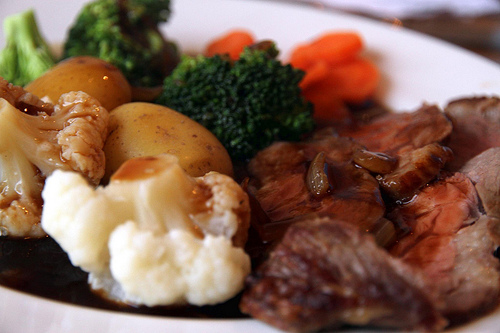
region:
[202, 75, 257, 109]
Piece of green broccoli on plate.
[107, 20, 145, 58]
Piece of green broccoli on side of plate.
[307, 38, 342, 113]
Carrot slices on plate.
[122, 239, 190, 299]
Piece of cauliflower on plate.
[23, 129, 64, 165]
Piece of cauliflower on plate.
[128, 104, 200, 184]
Small potato on plate.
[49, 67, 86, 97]
Small brown potato on plate.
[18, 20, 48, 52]
Piece of green broccoli on plate.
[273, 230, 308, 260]
Dark meat on top of white plate.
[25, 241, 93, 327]
Brown sauce on plate.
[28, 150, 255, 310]
a piece of cauliflower on the plate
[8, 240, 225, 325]
sauce on the plate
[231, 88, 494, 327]
a cut of meat on the plate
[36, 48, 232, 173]
two baby potatoes on the plate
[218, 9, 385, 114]
a group of sliced potatoes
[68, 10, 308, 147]
pieces of broccoli on the plate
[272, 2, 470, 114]
the edge of the plate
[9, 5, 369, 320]
mixed veggies with the meat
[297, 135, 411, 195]
some sliced vegges on the meat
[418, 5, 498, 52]
the table next to the plate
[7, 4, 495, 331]
food on a white plate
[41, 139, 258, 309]
piece of cauliflower with gravy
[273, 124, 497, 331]
beef on plate with gravy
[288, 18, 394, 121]
carrots on a plate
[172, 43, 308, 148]
piece of broccoli on a plate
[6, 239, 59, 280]
brown gravy on plate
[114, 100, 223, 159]
potato on a plate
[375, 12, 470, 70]
edge of white plate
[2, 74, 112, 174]
cauliflower smothered in gravy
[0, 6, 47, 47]
stalk of a piece of broccoli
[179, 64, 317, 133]
This is a green vegetable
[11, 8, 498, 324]
This is a white plate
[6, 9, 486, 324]
Plate full of food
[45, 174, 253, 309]
a piece of broccolli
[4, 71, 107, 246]
A piece of broccolli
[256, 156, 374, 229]
A piece of meat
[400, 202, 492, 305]
A piece of meat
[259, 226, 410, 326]
A piece of meat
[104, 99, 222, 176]
An unpeeled potato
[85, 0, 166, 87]
This is a piece of broccolli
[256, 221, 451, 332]
cooked beef on plate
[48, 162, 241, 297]
cauliflower on white plate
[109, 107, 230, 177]
potato on white plate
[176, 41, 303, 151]
broccoli on white plate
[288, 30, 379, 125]
carrots on white plate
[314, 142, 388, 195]
mushroom on cooked steak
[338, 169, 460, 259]
beef gravy on meat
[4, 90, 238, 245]
mushroom gravy on vegetables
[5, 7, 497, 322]
beef stew and vegetables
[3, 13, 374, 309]
mixed vegetables on plate